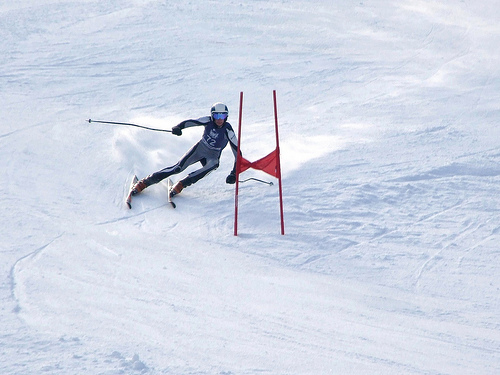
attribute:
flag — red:
[224, 89, 292, 241]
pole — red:
[229, 64, 264, 246]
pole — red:
[232, 94, 250, 240]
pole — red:
[263, 86, 297, 233]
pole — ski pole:
[65, 108, 196, 150]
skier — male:
[112, 158, 201, 218]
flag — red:
[208, 147, 289, 181]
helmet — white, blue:
[210, 102, 227, 119]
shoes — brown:
[127, 171, 191, 211]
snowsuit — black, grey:
[128, 113, 246, 208]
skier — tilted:
[122, 94, 241, 207]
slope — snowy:
[6, 5, 484, 367]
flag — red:
[239, 147, 278, 177]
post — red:
[272, 89, 286, 233]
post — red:
[233, 90, 246, 234]